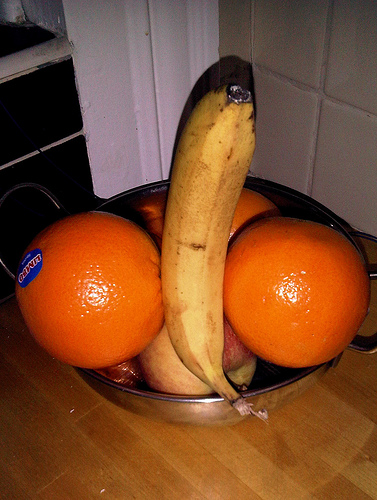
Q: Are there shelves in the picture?
A: No, there are no shelves.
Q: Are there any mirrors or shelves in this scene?
A: No, there are no shelves or mirrors.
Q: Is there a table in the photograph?
A: Yes, there is a table.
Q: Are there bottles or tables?
A: Yes, there is a table.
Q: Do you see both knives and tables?
A: No, there is a table but no knives.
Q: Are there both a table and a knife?
A: No, there is a table but no knives.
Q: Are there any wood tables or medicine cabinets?
A: Yes, there is a wood table.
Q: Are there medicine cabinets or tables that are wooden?
A: Yes, the table is wooden.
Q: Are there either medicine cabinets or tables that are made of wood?
A: Yes, the table is made of wood.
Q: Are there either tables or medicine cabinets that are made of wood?
A: Yes, the table is made of wood.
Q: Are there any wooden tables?
A: Yes, there is a wood table.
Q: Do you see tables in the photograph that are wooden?
A: Yes, there is a table that is wooden.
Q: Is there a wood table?
A: Yes, there is a table that is made of wood.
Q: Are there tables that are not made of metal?
A: Yes, there is a table that is made of wood.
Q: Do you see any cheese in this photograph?
A: No, there is no cheese.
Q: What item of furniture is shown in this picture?
A: The piece of furniture is a table.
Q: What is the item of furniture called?
A: The piece of furniture is a table.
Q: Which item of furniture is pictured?
A: The piece of furniture is a table.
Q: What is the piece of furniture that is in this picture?
A: The piece of furniture is a table.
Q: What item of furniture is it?
A: The piece of furniture is a table.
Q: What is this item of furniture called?
A: This is a table.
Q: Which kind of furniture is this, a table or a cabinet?
A: This is a table.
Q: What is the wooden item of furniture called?
A: The piece of furniture is a table.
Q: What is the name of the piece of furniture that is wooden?
A: The piece of furniture is a table.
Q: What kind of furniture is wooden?
A: The furniture is a table.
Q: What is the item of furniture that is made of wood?
A: The piece of furniture is a table.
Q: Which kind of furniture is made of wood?
A: The furniture is a table.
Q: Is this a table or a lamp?
A: This is a table.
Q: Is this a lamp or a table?
A: This is a table.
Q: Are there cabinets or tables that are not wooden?
A: No, there is a table but it is wooden.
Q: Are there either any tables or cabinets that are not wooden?
A: No, there is a table but it is wooden.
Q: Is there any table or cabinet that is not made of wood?
A: No, there is a table but it is made of wood.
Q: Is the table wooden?
A: Yes, the table is wooden.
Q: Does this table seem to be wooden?
A: Yes, the table is wooden.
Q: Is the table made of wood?
A: Yes, the table is made of wood.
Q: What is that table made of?
A: The table is made of wood.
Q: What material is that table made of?
A: The table is made of wood.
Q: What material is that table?
A: The table is made of wood.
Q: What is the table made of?
A: The table is made of wood.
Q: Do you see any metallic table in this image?
A: No, there is a table but it is wooden.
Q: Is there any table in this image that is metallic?
A: No, there is a table but it is wooden.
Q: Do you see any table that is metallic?
A: No, there is a table but it is wooden.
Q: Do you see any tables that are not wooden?
A: No, there is a table but it is wooden.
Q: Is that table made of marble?
A: No, the table is made of wood.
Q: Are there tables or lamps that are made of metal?
A: No, there is a table but it is made of wood.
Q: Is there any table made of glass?
A: No, there is a table but it is made of wood.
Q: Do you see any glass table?
A: No, there is a table but it is made of wood.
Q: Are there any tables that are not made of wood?
A: No, there is a table but it is made of wood.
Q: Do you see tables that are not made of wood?
A: No, there is a table but it is made of wood.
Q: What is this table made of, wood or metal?
A: The table is made of wood.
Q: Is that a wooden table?
A: Yes, that is a wooden table.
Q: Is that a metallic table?
A: No, that is a wooden table.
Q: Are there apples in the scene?
A: Yes, there is an apple.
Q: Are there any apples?
A: Yes, there is an apple.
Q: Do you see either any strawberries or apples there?
A: Yes, there is an apple.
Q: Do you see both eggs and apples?
A: No, there is an apple but no eggs.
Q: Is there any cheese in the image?
A: No, there is no cheese.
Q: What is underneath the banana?
A: The apple is underneath the banana.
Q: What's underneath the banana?
A: The apple is underneath the banana.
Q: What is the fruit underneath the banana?
A: The fruit is an apple.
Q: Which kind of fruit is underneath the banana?
A: The fruit is an apple.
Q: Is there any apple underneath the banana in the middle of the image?
A: Yes, there is an apple underneath the banana.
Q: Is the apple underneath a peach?
A: No, the apple is underneath the banana.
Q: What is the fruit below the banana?
A: The fruit is an apple.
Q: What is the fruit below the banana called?
A: The fruit is an apple.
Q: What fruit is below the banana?
A: The fruit is an apple.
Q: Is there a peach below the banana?
A: No, there is an apple below the banana.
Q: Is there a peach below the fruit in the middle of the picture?
A: No, there is an apple below the banana.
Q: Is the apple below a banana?
A: Yes, the apple is below a banana.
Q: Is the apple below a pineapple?
A: No, the apple is below a banana.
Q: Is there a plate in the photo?
A: No, there are no plates.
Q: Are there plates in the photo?
A: No, there are no plates.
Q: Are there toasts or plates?
A: No, there are no plates or toasts.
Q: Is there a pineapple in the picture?
A: No, there are no pineapples.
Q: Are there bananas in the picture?
A: Yes, there is a banana.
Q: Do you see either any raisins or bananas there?
A: Yes, there is a banana.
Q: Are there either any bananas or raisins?
A: Yes, there is a banana.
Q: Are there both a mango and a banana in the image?
A: No, there is a banana but no mangoes.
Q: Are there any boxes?
A: No, there are no boxes.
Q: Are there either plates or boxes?
A: No, there are no boxes or plates.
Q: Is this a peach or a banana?
A: This is a banana.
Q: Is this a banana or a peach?
A: This is a banana.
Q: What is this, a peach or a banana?
A: This is a banana.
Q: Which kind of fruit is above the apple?
A: The fruit is a banana.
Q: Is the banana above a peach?
A: No, the banana is above the apple.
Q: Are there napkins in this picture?
A: No, there are no napkins.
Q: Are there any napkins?
A: No, there are no napkins.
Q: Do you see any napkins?
A: No, there are no napkins.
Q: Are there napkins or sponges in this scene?
A: No, there are no napkins or sponges.